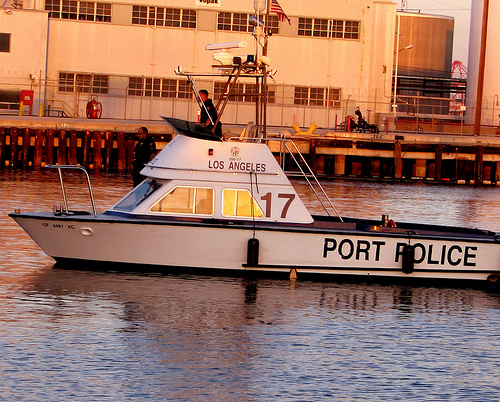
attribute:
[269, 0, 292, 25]
flag — american, blowing, america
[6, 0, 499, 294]
boat — sailing, white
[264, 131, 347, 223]
ladder — white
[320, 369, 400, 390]
ripples — tiny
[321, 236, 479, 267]
writing — black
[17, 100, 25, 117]
post — small, yellow